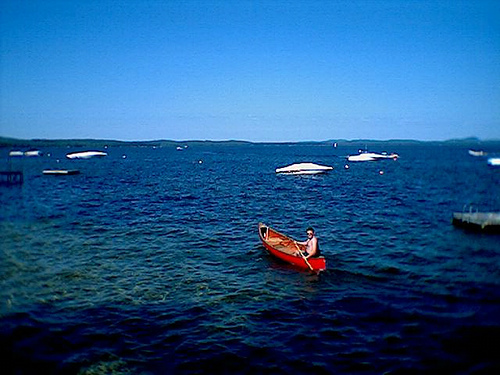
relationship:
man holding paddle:
[292, 226, 319, 259] [293, 234, 315, 276]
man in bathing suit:
[292, 226, 319, 259] [298, 251, 309, 257]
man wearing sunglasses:
[292, 226, 319, 259] [306, 231, 313, 235]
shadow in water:
[2, 272, 499, 371] [0, 138, 500, 373]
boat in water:
[254, 221, 329, 279] [0, 138, 500, 373]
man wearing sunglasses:
[287, 226, 329, 264] [304, 228, 319, 238]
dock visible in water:
[450, 201, 499, 232] [3, 210, 249, 371]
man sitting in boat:
[292, 226, 319, 259] [250, 217, 332, 277]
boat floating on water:
[254, 221, 327, 274] [43, 199, 210, 285]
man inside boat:
[292, 226, 319, 259] [256, 219, 319, 287]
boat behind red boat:
[275, 162, 335, 176] [253, 220, 329, 272]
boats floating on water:
[8, 141, 114, 188] [0, 138, 500, 373]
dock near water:
[450, 206, 500, 231] [170, 165, 278, 240]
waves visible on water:
[302, 181, 420, 223] [0, 138, 500, 373]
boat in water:
[254, 221, 327, 274] [82, 176, 212, 311]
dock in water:
[450, 206, 500, 231] [81, 200, 498, 374]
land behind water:
[9, 133, 486, 147] [0, 138, 500, 373]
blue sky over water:
[31, 110, 460, 154] [0, 138, 500, 373]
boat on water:
[275, 162, 335, 176] [0, 138, 500, 373]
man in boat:
[292, 226, 319, 259] [256, 226, 311, 263]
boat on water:
[271, 156, 335, 181] [0, 138, 500, 373]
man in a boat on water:
[292, 226, 319, 259] [0, 138, 500, 373]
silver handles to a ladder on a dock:
[466, 194, 484, 215] [435, 169, 496, 228]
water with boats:
[9, 126, 491, 349] [239, 212, 336, 283]